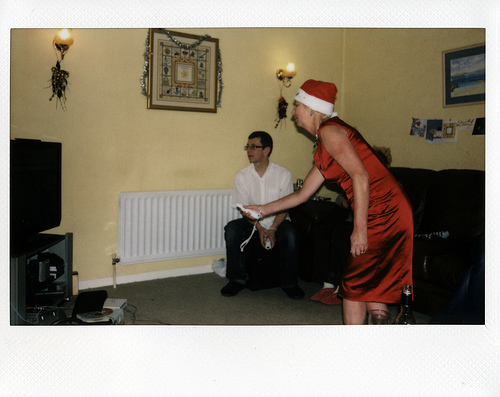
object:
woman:
[240, 78, 412, 325]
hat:
[294, 78, 339, 117]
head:
[288, 78, 339, 135]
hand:
[237, 200, 265, 220]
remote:
[234, 204, 264, 221]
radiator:
[118, 188, 242, 266]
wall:
[11, 28, 343, 290]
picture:
[148, 28, 217, 114]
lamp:
[52, 28, 75, 63]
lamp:
[276, 62, 297, 89]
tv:
[10, 138, 64, 236]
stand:
[10, 232, 75, 327]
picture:
[440, 42, 486, 108]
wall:
[337, 30, 483, 171]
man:
[217, 130, 305, 302]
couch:
[311, 167, 487, 318]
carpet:
[71, 272, 485, 325]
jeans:
[224, 215, 299, 291]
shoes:
[220, 278, 243, 299]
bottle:
[394, 283, 414, 325]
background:
[9, 28, 485, 326]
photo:
[409, 117, 427, 139]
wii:
[101, 298, 137, 308]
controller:
[264, 236, 273, 253]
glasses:
[242, 141, 267, 152]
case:
[73, 286, 113, 326]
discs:
[79, 306, 115, 319]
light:
[55, 28, 72, 40]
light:
[284, 59, 296, 74]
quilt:
[45, 62, 69, 113]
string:
[51, 44, 58, 62]